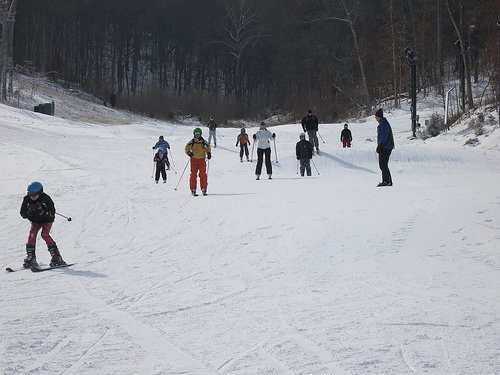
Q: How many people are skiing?
A: 11.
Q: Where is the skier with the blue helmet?
A: On the left.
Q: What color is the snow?
A: White.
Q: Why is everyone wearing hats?
A: It is cold.